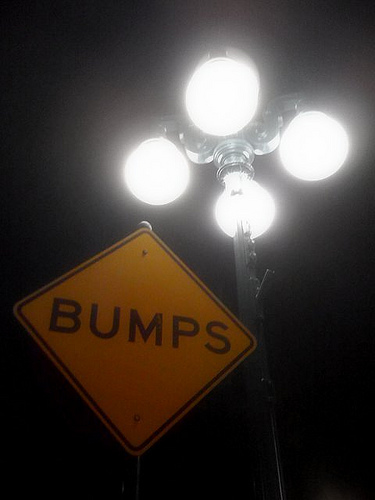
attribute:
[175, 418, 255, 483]
background — black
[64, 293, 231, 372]
yellow sign — yellow 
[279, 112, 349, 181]
post — tall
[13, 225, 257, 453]
sign — yellow and black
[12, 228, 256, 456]
boarder — dark